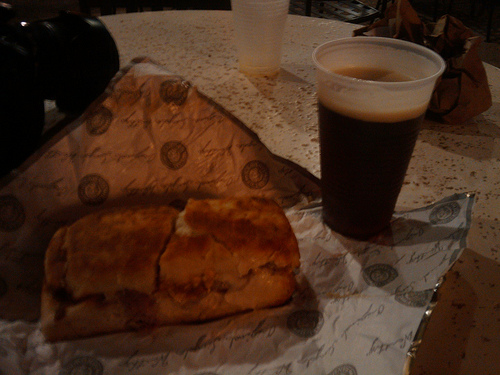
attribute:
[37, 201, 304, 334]
sandwich — cut, toasted, cracked, brown, thick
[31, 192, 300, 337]
bread — brown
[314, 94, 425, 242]
ale — dark, dark brown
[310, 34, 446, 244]
cup — plastic, disposable, full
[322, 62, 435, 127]
head — foamy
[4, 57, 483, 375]
paper — wrinkled, aluminum, white, foil, brown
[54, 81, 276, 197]
design — circle, grey, circular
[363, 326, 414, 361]
words — cursive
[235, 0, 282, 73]
cup — empty, plastic, clear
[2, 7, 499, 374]
table — ceramic, white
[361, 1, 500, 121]
bag — paper, crumpled, brown